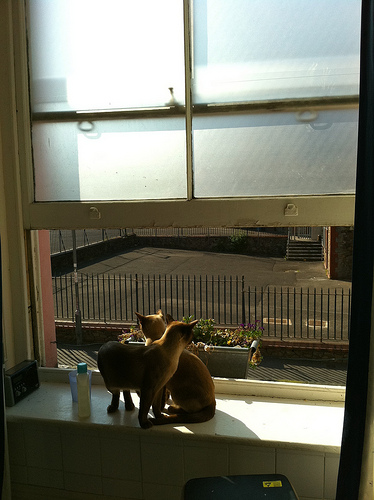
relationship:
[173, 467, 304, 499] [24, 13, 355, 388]
trash can beneath window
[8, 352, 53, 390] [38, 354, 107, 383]
black radio of window sill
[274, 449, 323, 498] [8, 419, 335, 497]
tile on wall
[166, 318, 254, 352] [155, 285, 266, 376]
flowers in garden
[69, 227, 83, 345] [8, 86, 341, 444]
pole outside building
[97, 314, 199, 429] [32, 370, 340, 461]
cat on ledge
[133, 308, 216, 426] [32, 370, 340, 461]
cat on ledge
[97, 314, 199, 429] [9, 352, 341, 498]
cat standing on ledge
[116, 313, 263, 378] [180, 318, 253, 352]
planter with plants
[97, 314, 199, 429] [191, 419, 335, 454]
cat on windowsill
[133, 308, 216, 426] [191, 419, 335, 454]
cat on windowsill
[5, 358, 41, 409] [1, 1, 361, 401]
black radio next to window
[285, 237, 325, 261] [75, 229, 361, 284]
stairs in background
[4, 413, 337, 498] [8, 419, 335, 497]
tiles on wall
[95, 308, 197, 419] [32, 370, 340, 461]
cat on ledge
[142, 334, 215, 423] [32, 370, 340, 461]
cat on ledge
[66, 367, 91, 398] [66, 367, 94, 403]
liquid in glass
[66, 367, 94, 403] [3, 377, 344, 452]
glass on ledge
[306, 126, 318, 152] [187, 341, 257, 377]
ground in planter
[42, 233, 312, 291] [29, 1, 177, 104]
glass covered in paper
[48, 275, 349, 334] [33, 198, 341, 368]
fence outside of window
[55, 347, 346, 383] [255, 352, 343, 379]
fence shadow on ground